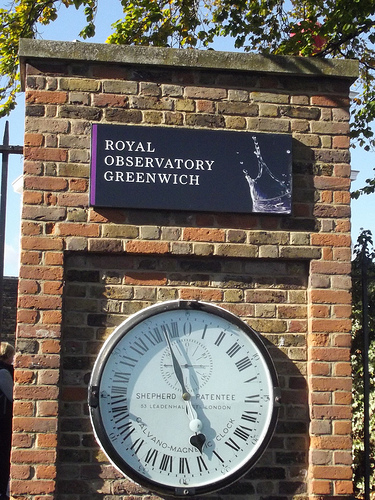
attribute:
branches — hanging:
[150, 0, 273, 45]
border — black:
[84, 286, 288, 498]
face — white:
[99, 311, 274, 487]